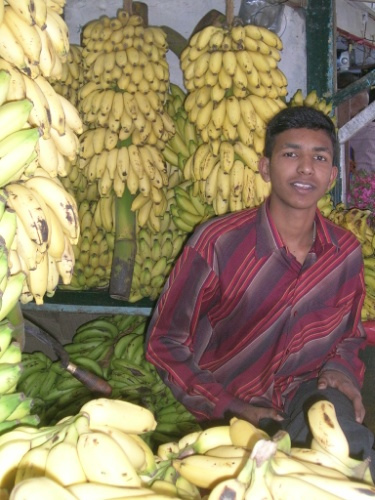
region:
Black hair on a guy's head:
[250, 97, 342, 214]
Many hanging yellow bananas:
[0, 0, 370, 327]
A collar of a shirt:
[246, 188, 342, 264]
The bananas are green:
[15, 307, 203, 457]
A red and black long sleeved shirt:
[140, 187, 369, 430]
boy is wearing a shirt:
[163, 108, 360, 421]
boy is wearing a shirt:
[183, 94, 344, 434]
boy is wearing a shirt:
[175, 115, 329, 434]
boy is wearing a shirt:
[156, 95, 357, 446]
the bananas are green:
[62, 319, 156, 425]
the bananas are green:
[68, 311, 160, 413]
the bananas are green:
[71, 308, 169, 426]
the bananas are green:
[75, 307, 166, 405]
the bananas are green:
[78, 335, 170, 433]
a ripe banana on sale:
[165, 457, 261, 477]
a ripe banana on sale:
[224, 414, 256, 448]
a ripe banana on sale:
[197, 442, 246, 470]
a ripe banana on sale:
[311, 393, 352, 475]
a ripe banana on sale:
[72, 430, 125, 493]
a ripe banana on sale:
[85, 392, 160, 431]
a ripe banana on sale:
[115, 424, 161, 477]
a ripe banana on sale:
[172, 452, 241, 482]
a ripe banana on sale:
[183, 419, 237, 467]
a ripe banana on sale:
[178, 431, 204, 446]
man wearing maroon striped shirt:
[144, 213, 372, 433]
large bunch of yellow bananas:
[77, 2, 171, 201]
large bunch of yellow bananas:
[181, 3, 292, 210]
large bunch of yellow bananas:
[2, 176, 83, 296]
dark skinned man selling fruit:
[146, 90, 371, 443]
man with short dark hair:
[257, 105, 338, 152]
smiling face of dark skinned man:
[271, 126, 342, 197]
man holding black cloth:
[248, 367, 371, 454]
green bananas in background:
[28, 315, 210, 433]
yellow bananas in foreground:
[1, 397, 371, 494]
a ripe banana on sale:
[174, 458, 232, 483]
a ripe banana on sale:
[302, 398, 345, 450]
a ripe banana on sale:
[223, 472, 249, 499]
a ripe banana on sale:
[263, 474, 297, 497]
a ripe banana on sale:
[229, 414, 266, 452]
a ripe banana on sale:
[205, 443, 252, 463]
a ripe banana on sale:
[107, 425, 148, 462]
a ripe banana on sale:
[78, 427, 136, 489]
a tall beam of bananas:
[81, 1, 171, 297]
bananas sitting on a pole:
[72, 5, 174, 303]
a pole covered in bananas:
[71, 3, 172, 309]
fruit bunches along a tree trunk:
[79, 3, 175, 308]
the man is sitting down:
[143, 106, 373, 459]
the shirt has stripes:
[144, 193, 365, 422]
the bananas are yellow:
[0, 0, 372, 498]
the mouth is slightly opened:
[290, 179, 317, 194]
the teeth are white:
[293, 182, 313, 190]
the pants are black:
[260, 376, 373, 468]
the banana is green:
[196, 26, 220, 51]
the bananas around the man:
[0, 0, 373, 498]